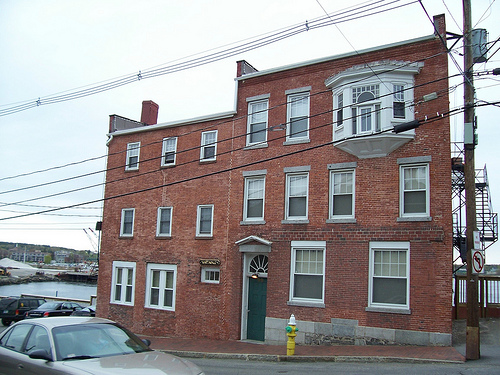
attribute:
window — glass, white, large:
[247, 93, 271, 146]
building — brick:
[93, 7, 460, 348]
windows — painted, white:
[152, 200, 213, 241]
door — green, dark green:
[247, 275, 269, 340]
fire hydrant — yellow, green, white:
[287, 313, 297, 354]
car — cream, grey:
[3, 303, 209, 371]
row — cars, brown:
[0, 298, 94, 328]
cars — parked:
[2, 294, 95, 331]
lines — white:
[253, 104, 269, 123]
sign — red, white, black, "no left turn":
[470, 249, 486, 272]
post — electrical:
[461, 0, 483, 365]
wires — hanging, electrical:
[4, 0, 495, 225]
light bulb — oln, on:
[253, 272, 258, 279]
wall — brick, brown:
[12, 294, 95, 322]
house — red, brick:
[89, 145, 460, 352]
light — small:
[250, 273, 257, 280]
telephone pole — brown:
[458, 0, 484, 358]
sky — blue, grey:
[7, 0, 481, 251]